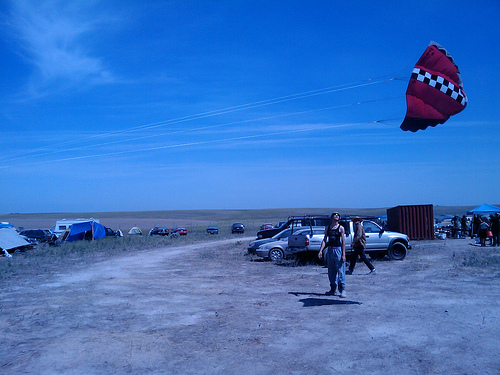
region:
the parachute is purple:
[376, 54, 494, 146]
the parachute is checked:
[407, 61, 474, 107]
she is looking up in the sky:
[305, 198, 369, 306]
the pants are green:
[317, 244, 357, 289]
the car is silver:
[300, 219, 410, 267]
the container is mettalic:
[387, 189, 445, 249]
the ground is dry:
[119, 270, 284, 374]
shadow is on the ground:
[280, 288, 387, 320]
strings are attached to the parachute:
[175, 67, 367, 147]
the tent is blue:
[60, 214, 115, 243]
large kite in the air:
[382, 17, 471, 148]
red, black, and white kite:
[372, 23, 470, 148]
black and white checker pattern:
[402, 61, 476, 108]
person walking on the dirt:
[346, 215, 382, 284]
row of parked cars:
[237, 199, 404, 275]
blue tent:
[465, 196, 499, 233]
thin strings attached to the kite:
[3, 43, 421, 200]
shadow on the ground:
[298, 292, 354, 309]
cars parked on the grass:
[136, 221, 253, 241]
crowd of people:
[444, 206, 496, 249]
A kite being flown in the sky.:
[397, 42, 467, 138]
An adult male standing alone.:
[319, 208, 352, 303]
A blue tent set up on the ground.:
[63, 219, 118, 239]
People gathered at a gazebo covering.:
[467, 204, 497, 246]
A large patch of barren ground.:
[1, 290, 498, 372]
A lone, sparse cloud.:
[1, 0, 137, 90]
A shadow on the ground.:
[298, 293, 362, 312]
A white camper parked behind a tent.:
[52, 218, 102, 233]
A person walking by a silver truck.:
[345, 218, 375, 271]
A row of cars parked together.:
[178, 223, 266, 235]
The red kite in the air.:
[385, 35, 471, 137]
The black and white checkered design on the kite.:
[414, 67, 465, 108]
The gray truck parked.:
[291, 211, 410, 263]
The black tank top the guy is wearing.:
[322, 224, 344, 245]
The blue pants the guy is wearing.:
[320, 243, 345, 288]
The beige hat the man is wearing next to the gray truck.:
[352, 213, 367, 224]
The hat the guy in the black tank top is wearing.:
[331, 210, 342, 218]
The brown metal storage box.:
[387, 202, 438, 242]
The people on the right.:
[430, 204, 497, 239]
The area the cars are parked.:
[16, 180, 496, 373]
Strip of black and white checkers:
[408, 65, 467, 106]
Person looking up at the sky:
[317, 208, 349, 298]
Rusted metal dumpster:
[384, 202, 435, 242]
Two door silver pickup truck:
[285, 215, 412, 260]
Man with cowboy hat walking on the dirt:
[346, 211, 375, 278]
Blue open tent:
[62, 221, 108, 243]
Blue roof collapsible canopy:
[464, 201, 499, 241]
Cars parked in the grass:
[150, 221, 275, 236]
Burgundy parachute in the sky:
[2, 38, 471, 138]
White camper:
[51, 216, 101, 243]